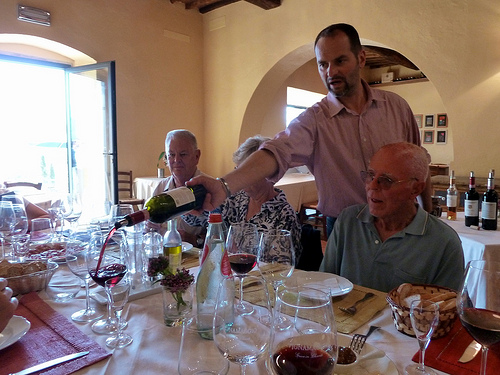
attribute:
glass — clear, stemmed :
[256, 219, 294, 341]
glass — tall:
[88, 227, 131, 330]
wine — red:
[91, 260, 128, 287]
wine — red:
[274, 344, 333, 373]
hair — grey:
[162, 129, 197, 145]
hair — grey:
[315, 26, 363, 47]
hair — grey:
[384, 141, 429, 174]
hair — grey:
[235, 141, 265, 160]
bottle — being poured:
[117, 179, 212, 238]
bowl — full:
[380, 272, 459, 357]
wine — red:
[103, 184, 216, 256]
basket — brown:
[4, 245, 60, 286]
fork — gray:
[348, 319, 383, 357]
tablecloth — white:
[0, 213, 422, 374]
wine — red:
[88, 264, 129, 282]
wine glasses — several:
[56, 219, 363, 356]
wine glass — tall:
[86, 227, 137, 351]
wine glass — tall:
[217, 220, 261, 317]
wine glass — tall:
[253, 222, 299, 314]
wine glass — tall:
[265, 275, 344, 374]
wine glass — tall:
[52, 188, 85, 245]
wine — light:
[226, 252, 258, 274]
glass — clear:
[213, 275, 273, 365]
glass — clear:
[263, 285, 353, 371]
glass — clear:
[224, 214, 260, 314]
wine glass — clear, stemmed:
[406, 297, 442, 374]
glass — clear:
[161, 286, 193, 324]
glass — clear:
[407, 297, 441, 370]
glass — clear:
[83, 232, 134, 337]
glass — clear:
[258, 228, 299, 317]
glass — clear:
[218, 220, 260, 312]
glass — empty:
[214, 274, 271, 374]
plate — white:
[277, 265, 348, 295]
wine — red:
[269, 342, 334, 370]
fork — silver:
[337, 324, 376, 354]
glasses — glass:
[357, 167, 422, 189]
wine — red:
[88, 227, 127, 284]